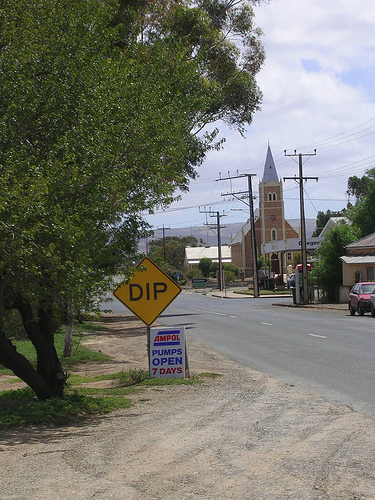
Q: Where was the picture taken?
A: It was taken at the road.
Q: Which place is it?
A: It is a road.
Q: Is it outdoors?
A: Yes, it is outdoors.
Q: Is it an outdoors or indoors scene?
A: It is outdoors.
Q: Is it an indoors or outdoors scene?
A: It is outdoors.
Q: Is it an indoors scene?
A: No, it is outdoors.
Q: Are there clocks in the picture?
A: No, there are no clocks.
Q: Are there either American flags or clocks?
A: No, there are no clocks or American flags.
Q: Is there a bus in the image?
A: No, there are no buses.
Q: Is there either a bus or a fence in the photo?
A: No, there are no buses or fences.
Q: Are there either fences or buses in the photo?
A: No, there are no buses or fences.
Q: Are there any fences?
A: No, there are no fences.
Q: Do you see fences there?
A: No, there are no fences.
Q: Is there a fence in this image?
A: No, there are no fences.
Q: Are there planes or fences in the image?
A: No, there are no fences or planes.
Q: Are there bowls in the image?
A: No, there are no bowls.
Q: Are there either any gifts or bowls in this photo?
A: No, there are no bowls or gifts.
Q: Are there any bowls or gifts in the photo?
A: No, there are no bowls or gifts.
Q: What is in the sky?
A: The clouds are in the sky.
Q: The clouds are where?
A: The clouds are in the sky.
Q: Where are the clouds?
A: The clouds are in the sky.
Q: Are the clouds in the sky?
A: Yes, the clouds are in the sky.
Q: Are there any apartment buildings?
A: No, there are no apartment buildings.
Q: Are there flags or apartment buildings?
A: No, there are no apartment buildings or flags.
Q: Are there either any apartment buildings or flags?
A: No, there are no apartment buildings or flags.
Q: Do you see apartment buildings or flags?
A: No, there are no apartment buildings or flags.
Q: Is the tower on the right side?
A: Yes, the tower is on the right of the image.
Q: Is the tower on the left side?
A: No, the tower is on the right of the image.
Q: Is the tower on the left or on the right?
A: The tower is on the right of the image.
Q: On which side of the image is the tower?
A: The tower is on the right of the image.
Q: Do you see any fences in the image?
A: No, there are no fences.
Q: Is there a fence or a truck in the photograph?
A: No, there are no fences or trucks.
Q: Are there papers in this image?
A: No, there are no papers.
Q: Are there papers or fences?
A: No, there are no papers or fences.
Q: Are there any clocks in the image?
A: No, there are no clocks.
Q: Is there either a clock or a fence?
A: No, there are no clocks or fences.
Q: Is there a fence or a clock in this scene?
A: No, there are no clocks or fences.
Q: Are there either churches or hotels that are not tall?
A: No, there is a church but it is tall.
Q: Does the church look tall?
A: Yes, the church is tall.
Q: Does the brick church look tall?
A: Yes, the church is tall.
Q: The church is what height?
A: The church is tall.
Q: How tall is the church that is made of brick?
A: The church is tall.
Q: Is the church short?
A: No, the church is tall.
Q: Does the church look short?
A: No, the church is tall.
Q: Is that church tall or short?
A: The church is tall.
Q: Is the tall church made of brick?
A: Yes, the church is made of brick.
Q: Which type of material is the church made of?
A: The church is made of brick.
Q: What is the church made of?
A: The church is made of brick.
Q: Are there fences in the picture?
A: No, there are no fences.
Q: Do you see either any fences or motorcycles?
A: No, there are no fences or motorcycles.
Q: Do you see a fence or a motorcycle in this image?
A: No, there are no fences or motorcycles.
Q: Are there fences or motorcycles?
A: No, there are no fences or motorcycles.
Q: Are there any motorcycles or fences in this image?
A: No, there are no fences or motorcycles.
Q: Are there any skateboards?
A: No, there are no skateboards.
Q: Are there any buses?
A: No, there are no buses.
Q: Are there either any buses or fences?
A: No, there are no buses or fences.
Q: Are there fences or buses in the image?
A: No, there are no buses or fences.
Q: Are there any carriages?
A: No, there are no carriages.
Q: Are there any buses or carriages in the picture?
A: No, there are no carriages or buses.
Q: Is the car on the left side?
A: No, the car is on the right of the image.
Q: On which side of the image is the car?
A: The car is on the right of the image.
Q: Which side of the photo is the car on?
A: The car is on the right of the image.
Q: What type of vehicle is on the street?
A: The vehicle is a car.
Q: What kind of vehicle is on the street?
A: The vehicle is a car.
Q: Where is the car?
A: The car is on the street.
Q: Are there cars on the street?
A: Yes, there is a car on the street.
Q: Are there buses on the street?
A: No, there is a car on the street.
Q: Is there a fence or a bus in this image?
A: No, there are no fences or buses.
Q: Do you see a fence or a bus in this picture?
A: No, there are no fences or buses.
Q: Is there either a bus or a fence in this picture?
A: No, there are no fences or buses.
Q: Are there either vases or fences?
A: No, there are no fences or vases.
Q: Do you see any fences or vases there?
A: No, there are no fences or vases.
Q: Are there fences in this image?
A: No, there are no fences.